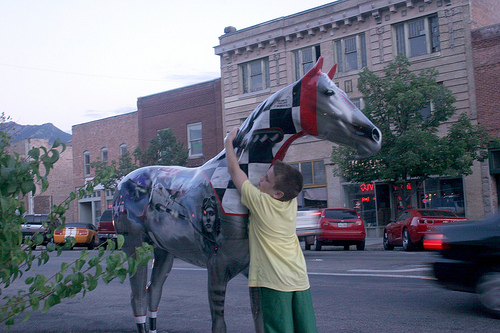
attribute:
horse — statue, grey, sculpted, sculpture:
[110, 55, 382, 331]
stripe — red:
[298, 53, 324, 140]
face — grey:
[313, 70, 383, 157]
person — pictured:
[200, 197, 220, 252]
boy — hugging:
[225, 126, 317, 332]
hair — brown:
[271, 156, 305, 204]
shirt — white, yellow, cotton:
[238, 180, 310, 294]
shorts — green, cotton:
[256, 284, 319, 332]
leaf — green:
[114, 232, 127, 249]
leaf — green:
[96, 244, 107, 262]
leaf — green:
[50, 147, 61, 167]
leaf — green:
[41, 174, 50, 197]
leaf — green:
[18, 180, 34, 198]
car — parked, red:
[383, 205, 469, 250]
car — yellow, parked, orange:
[52, 220, 101, 251]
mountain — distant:
[1, 120, 73, 153]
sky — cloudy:
[0, 1, 335, 135]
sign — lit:
[358, 182, 376, 194]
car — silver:
[16, 213, 61, 250]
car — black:
[417, 214, 499, 314]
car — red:
[302, 204, 370, 253]